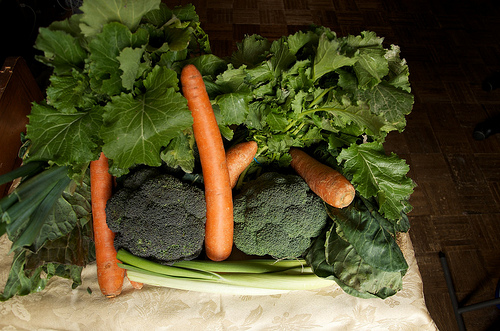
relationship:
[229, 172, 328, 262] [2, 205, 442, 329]
veggie on table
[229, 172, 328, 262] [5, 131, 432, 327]
veggie on table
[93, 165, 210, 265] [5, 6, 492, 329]
veggie on table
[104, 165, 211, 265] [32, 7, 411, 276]
veggie in pile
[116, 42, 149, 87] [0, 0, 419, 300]
green leaf in pile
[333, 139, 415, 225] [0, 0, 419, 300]
green leaf in pile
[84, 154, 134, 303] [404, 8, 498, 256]
orange veggie on table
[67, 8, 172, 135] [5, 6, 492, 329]
veggie on table